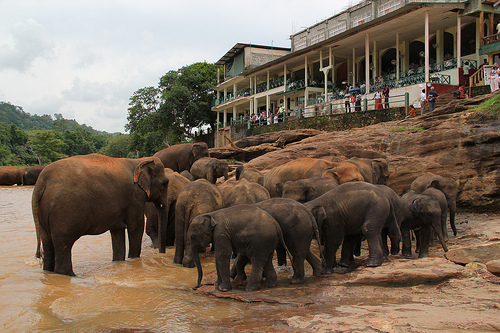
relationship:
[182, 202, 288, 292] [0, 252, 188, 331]
baby elephant on edge of water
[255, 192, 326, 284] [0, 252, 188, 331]
baby elephant on edge of water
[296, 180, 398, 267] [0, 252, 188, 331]
baby elephant on edge of water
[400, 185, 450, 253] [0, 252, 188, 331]
baby elephant on edge of water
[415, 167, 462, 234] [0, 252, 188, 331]
baby elephant on edge of water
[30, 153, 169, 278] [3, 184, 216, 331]
elephant standing in water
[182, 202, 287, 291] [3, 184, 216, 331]
baby elephant standing in water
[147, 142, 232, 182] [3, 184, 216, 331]
elephant standing in water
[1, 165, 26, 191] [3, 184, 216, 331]
elephant standing in water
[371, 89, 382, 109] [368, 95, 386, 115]
person wearing a skirt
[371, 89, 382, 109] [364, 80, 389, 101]
person wearing a top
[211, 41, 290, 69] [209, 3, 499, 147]
roof on top of building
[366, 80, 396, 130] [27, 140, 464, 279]
person watching elephants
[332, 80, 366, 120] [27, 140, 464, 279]
person watching elephants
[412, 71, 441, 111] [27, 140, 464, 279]
person watching elephants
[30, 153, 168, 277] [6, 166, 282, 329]
elephant standing in water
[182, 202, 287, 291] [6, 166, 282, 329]
baby elephant standing in water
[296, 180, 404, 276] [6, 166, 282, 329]
baby elephant standing in water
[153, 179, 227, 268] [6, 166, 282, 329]
elephant standing in water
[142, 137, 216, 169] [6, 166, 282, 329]
elephant standing in water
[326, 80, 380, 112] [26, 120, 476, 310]
person watching elephants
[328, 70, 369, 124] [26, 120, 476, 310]
person watching elephants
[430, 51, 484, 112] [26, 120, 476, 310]
person watching elephants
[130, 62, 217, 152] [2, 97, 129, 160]
trees on top of mountain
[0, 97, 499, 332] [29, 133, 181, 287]
mud on elephant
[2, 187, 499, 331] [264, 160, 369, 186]
mud on elephant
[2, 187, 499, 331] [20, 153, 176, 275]
mud on elephant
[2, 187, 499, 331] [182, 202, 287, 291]
mud on baby elephant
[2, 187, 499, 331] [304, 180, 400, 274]
mud on elephant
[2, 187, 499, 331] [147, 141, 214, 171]
mud on elephant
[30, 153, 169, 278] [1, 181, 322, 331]
elephant in water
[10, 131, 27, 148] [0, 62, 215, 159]
leaves on trees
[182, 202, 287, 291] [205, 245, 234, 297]
baby elephant has legs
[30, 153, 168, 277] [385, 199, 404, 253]
elephant has tail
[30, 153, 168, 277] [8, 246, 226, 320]
elephant drink water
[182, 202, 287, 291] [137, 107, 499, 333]
baby elephant on rocky area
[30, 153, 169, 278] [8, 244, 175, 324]
elephant on water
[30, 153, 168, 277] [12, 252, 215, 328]
elephant in water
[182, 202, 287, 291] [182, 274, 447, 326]
baby elephant on rocky area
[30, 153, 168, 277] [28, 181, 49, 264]
elephant has tail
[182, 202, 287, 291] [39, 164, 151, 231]
baby elephant has side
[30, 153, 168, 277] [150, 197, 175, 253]
elephant has trunk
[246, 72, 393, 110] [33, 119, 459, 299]
crowd watch elephants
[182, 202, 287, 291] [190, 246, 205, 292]
baby elephant has trunk